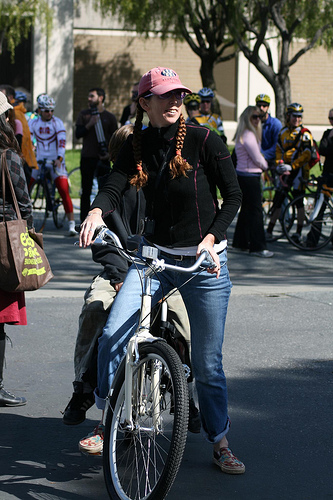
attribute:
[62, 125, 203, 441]
person — paritally visible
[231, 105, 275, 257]
woman — standing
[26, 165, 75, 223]
pants — red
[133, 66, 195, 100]
hat — pink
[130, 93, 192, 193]
hair — braided, long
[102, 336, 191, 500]
wheel — black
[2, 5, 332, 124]
trees — green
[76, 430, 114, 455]
show — canvas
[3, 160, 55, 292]
bag — brown, yellow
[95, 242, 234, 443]
jeans — blue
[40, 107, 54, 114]
sunglasses — black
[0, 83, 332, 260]
people — gathered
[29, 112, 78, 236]
outfit — red, white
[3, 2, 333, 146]
building — brown, white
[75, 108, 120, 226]
clothes — dark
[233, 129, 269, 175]
top — pink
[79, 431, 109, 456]
shoe — multi colored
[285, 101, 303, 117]
helmet — silver, yellow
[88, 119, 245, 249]
shirt — black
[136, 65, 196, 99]
cap — pink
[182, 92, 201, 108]
helmet — colorful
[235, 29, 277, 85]
branch — gray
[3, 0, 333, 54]
leaves — green